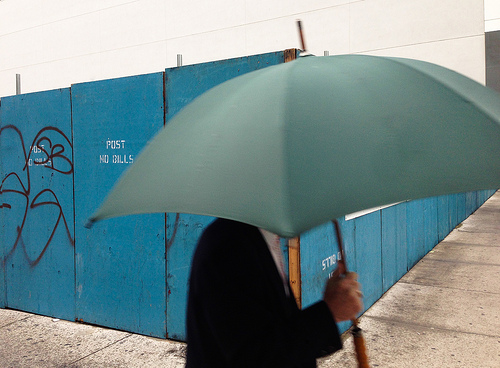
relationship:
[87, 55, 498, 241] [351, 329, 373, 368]
umbrella has a handle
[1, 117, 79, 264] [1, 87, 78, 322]
graffiti on wall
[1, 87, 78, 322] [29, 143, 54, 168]
wall has writing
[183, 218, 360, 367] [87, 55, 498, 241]
man holding umbrella